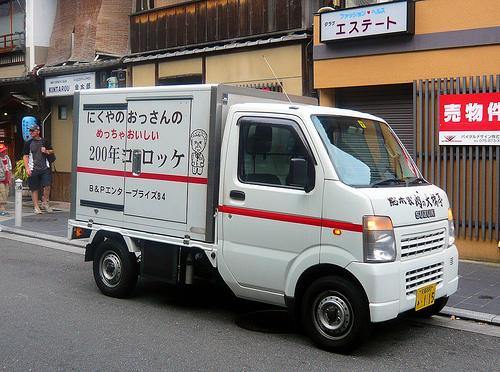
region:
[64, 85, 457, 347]
the white truck on the road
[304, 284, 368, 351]
the front right tire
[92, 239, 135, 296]
the back right tire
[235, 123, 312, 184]
the passengers window on the truck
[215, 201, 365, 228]
the red stripe on the passengers side of the truck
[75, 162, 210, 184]
the red stripe on the side of the truck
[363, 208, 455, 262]
the headlights on the truck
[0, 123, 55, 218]
the people on the sidewalk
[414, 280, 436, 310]
the yellow license plate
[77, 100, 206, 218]
the asian writing on the side of the truck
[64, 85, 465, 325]
white truck with red stripe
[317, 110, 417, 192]
front window of white truck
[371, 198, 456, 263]
front lights of white truck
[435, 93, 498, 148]
red sign with white lettering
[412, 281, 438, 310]
front yellow license plate of white truck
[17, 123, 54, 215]
man walking down sidewalk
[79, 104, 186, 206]
black and red lettering on side of white truck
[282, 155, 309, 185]
sideview mirror on truck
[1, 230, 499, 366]
street white truck is parked on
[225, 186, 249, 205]
black doorhandle of white truck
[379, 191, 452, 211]
chinese characters on the front of the vehicle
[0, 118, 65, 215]
two people walking on the sidewalk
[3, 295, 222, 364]
black asphalt of the road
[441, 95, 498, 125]
red sign with white lettering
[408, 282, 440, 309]
license plate of the vehicle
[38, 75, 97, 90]
white sign with black lettering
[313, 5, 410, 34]
white sign with blue and red lettering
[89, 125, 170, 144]
red lettering on the side of the vehicle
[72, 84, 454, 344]
white food delivery vehicle with chinese lettering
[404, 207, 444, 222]
brand of the vehicle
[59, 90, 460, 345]
white truck on the street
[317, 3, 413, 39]
sign on the building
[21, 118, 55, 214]
person standing on the sidewalk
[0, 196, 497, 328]
sidewalk next to the stores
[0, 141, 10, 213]
person walking on the sidewalk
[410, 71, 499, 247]
metal bars on the building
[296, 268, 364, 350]
front right wheels of the vehicle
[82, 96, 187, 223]
text on the side of the truck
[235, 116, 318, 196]
front passenger side window of the truck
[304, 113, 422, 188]
front window fo the truck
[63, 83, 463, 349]
white truck on street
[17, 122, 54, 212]
person standing on sidewalk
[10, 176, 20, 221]
white pole in sidewalk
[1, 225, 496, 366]
black paved street next to sidewalk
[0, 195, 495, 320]
gray concrete sidewalk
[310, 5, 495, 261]
orange building behind truck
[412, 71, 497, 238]
metal gate on orange building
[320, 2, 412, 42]
white rectangle sign on building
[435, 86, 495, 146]
red and white sign on gate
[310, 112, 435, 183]
glass windshield on truck